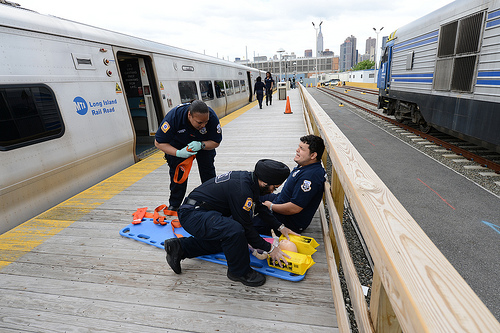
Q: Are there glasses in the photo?
A: No, there are no glasses.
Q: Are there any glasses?
A: No, there are no glasses.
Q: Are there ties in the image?
A: Yes, there is a tie.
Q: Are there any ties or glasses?
A: Yes, there is a tie.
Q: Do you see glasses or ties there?
A: Yes, there is a tie.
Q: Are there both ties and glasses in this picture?
A: No, there is a tie but no glasses.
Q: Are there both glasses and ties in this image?
A: No, there is a tie but no glasses.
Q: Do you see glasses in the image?
A: No, there are no glasses.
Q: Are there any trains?
A: Yes, there is a train.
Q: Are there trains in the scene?
A: Yes, there is a train.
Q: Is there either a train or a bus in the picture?
A: Yes, there is a train.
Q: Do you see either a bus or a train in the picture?
A: Yes, there is a train.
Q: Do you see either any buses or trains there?
A: Yes, there is a train.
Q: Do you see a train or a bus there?
A: Yes, there is a train.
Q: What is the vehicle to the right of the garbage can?
A: The vehicle is a train.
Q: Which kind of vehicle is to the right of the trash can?
A: The vehicle is a train.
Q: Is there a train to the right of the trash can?
A: Yes, there is a train to the right of the trash can.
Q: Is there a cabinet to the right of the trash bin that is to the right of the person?
A: No, there is a train to the right of the trash can.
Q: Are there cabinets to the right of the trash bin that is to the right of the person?
A: No, there is a train to the right of the trash can.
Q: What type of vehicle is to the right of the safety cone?
A: The vehicle is a train.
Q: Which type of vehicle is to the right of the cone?
A: The vehicle is a train.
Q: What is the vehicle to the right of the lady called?
A: The vehicle is a train.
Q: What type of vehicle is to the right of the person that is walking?
A: The vehicle is a train.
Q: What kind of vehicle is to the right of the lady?
A: The vehicle is a train.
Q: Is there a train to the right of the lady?
A: Yes, there is a train to the right of the lady.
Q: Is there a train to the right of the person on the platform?
A: Yes, there is a train to the right of the lady.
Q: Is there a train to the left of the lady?
A: No, the train is to the right of the lady.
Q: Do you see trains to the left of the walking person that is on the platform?
A: No, the train is to the right of the lady.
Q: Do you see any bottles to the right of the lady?
A: No, there is a train to the right of the lady.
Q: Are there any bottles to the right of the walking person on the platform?
A: No, there is a train to the right of the lady.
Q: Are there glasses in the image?
A: No, there are no glasses.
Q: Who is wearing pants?
A: The man is wearing pants.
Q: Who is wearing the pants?
A: The man is wearing pants.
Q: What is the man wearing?
A: The man is wearing trousers.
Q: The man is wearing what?
A: The man is wearing trousers.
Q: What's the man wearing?
A: The man is wearing trousers.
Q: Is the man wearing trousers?
A: Yes, the man is wearing trousers.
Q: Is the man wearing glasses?
A: No, the man is wearing trousers.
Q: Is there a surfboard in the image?
A: No, there are no surfboards.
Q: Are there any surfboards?
A: No, there are no surfboards.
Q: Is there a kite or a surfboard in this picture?
A: No, there are no surfboards or kites.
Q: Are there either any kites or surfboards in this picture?
A: No, there are no surfboards or kites.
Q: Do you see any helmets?
A: No, there are no helmets.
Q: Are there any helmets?
A: No, there are no helmets.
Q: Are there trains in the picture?
A: Yes, there is a train.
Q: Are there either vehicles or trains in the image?
A: Yes, there is a train.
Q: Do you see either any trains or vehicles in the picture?
A: Yes, there is a train.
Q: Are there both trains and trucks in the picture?
A: No, there is a train but no trucks.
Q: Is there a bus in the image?
A: No, there are no buses.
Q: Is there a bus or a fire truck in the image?
A: No, there are no buses or fire trucks.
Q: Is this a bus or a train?
A: This is a train.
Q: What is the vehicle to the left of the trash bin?
A: The vehicle is a train.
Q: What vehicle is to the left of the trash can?
A: The vehicle is a train.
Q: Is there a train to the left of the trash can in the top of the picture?
A: Yes, there is a train to the left of the trashcan.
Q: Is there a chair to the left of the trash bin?
A: No, there is a train to the left of the trash bin.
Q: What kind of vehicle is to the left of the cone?
A: The vehicle is a train.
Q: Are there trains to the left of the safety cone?
A: Yes, there is a train to the left of the safety cone.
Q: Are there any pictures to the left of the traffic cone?
A: No, there is a train to the left of the traffic cone.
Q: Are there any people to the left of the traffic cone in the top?
A: Yes, there is a person to the left of the safety cone.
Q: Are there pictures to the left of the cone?
A: No, there is a person to the left of the cone.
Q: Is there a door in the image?
A: Yes, there is a door.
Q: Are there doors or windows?
A: Yes, there is a door.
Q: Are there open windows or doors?
A: Yes, there is an open door.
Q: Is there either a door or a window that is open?
A: Yes, the door is open.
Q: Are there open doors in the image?
A: Yes, there is an open door.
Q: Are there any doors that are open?
A: Yes, there is a door that is open.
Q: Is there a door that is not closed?
A: Yes, there is a open door.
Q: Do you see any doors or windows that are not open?
A: No, there is a door but it is open.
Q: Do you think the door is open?
A: Yes, the door is open.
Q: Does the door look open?
A: Yes, the door is open.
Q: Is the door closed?
A: No, the door is open.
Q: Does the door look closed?
A: No, the door is open.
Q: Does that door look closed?
A: No, the door is open.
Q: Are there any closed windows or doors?
A: No, there is a door but it is open.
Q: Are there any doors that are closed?
A: No, there is a door but it is open.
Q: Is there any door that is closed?
A: No, there is a door but it is open.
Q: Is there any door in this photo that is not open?
A: No, there is a door but it is open.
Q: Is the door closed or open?
A: The door is open.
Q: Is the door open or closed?
A: The door is open.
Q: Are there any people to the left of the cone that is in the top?
A: Yes, there is a person to the left of the safety cone.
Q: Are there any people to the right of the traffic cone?
A: No, the person is to the left of the traffic cone.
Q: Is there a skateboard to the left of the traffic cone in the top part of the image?
A: No, there is a person to the left of the traffic cone.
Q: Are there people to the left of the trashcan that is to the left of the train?
A: Yes, there is a person to the left of the trash can.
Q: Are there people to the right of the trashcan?
A: No, the person is to the left of the trashcan.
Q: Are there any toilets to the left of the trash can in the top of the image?
A: No, there is a person to the left of the trash bin.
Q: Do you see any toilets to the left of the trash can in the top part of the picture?
A: No, there is a person to the left of the trash bin.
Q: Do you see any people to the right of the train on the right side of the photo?
A: No, the person is to the left of the train.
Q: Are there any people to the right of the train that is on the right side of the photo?
A: No, the person is to the left of the train.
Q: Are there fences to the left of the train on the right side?
A: No, there is a person to the left of the train.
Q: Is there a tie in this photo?
A: Yes, there is a tie.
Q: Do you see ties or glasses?
A: Yes, there is a tie.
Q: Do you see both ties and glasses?
A: No, there is a tie but no glasses.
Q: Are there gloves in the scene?
A: Yes, there are gloves.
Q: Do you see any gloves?
A: Yes, there are gloves.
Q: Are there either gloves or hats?
A: Yes, there are gloves.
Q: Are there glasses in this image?
A: No, there are no glasses.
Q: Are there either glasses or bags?
A: No, there are no glasses or bags.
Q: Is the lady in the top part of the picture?
A: Yes, the lady is in the top of the image.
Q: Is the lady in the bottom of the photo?
A: No, the lady is in the top of the image.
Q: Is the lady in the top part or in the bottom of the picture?
A: The lady is in the top of the image.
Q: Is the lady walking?
A: Yes, the lady is walking.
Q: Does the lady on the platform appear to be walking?
A: Yes, the lady is walking.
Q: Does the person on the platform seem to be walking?
A: Yes, the lady is walking.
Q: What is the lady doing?
A: The lady is walking.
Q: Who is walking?
A: The lady is walking.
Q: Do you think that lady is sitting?
A: No, the lady is walking.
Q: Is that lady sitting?
A: No, the lady is walking.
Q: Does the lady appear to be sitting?
A: No, the lady is walking.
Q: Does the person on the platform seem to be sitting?
A: No, the lady is walking.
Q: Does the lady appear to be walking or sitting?
A: The lady is walking.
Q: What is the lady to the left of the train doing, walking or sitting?
A: The lady is walking.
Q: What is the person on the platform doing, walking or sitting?
A: The lady is walking.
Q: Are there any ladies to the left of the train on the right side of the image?
A: Yes, there is a lady to the left of the train.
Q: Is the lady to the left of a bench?
A: No, the lady is to the left of the train.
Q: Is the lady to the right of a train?
A: No, the lady is to the left of a train.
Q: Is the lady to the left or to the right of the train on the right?
A: The lady is to the left of the train.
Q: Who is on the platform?
A: The lady is on the platform.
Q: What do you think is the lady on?
A: The lady is on the platform.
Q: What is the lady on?
A: The lady is on the platform.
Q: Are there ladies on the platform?
A: Yes, there is a lady on the platform.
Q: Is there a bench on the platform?
A: No, there is a lady on the platform.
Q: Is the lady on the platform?
A: Yes, the lady is on the platform.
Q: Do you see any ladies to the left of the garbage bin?
A: Yes, there is a lady to the left of the garbage bin.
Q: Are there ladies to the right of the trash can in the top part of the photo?
A: No, the lady is to the left of the trashcan.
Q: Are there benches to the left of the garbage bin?
A: No, there is a lady to the left of the garbage bin.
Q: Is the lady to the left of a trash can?
A: Yes, the lady is to the left of a trash can.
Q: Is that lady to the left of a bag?
A: No, the lady is to the left of a trash can.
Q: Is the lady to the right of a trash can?
A: No, the lady is to the left of a trash can.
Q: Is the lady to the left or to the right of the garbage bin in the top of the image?
A: The lady is to the left of the garbage bin.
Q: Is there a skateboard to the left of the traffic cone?
A: No, there is a lady to the left of the traffic cone.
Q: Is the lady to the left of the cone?
A: Yes, the lady is to the left of the cone.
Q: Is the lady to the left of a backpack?
A: No, the lady is to the left of the cone.